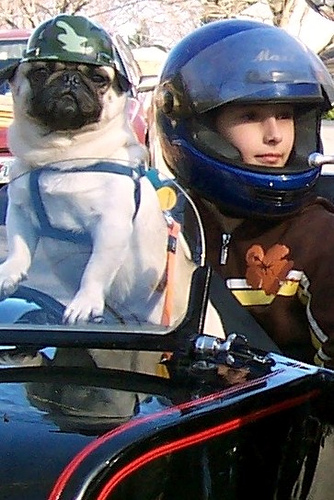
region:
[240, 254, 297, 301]
flower is on shirt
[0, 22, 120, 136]
helmet is on dog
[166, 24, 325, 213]
helmet is on person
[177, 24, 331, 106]
visor is on helmet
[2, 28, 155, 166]
the car is red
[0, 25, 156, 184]
the car behind dog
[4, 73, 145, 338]
dog behind steering wheel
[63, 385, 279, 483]
the stripe is red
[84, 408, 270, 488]
stripe is on vehicle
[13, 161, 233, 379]
windshield on the vehicle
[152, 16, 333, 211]
A woman with a blue helmet.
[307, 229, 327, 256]
Part of the jacket.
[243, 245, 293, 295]
A flower on the jacket.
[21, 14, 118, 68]
A green helmet.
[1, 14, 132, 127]
A dog wearing a helmet.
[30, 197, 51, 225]
Part of the dog harness.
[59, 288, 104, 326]
The dog's white paw.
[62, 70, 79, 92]
The dog's black nose.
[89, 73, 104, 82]
The eye of the dog.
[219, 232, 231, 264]
A silver zipper.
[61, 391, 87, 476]
This vehicle has a bright, black color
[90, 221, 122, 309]
This dog has a light grey coat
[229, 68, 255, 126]
This person is wearing a blue helmet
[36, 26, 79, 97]
This dog has a helmet on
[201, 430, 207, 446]
There is a red stripe that is on the car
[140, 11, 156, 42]
There are some bright trees in the background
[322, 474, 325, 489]
There is some concrete visible here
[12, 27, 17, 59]
There is a red car that is visible here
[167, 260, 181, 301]
There is an orange leash here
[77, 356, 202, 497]
Jackson Mingus took this photo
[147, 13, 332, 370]
young girl wearing a blue helmet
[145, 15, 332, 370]
young girl wearing a brown jacket with white and yellow stripe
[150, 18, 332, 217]
young girls blue helmet with face shield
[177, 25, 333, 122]
clear face shield on the blue helmet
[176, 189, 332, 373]
Brown jacket with yellow and white stripe the girl is wearing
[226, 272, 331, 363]
white stripe on the childs brown jacket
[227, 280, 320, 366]
yellow stripe on the childs brown jacket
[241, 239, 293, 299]
light brown orangish colored flower on childs jacket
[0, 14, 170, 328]
small white dog wearing a camo style hat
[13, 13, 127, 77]
hat that the dog is wearing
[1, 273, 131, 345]
paws on the wheel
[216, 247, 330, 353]
stripes on the sweater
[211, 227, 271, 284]
zipper on the sweater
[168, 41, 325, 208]
the helmet is blue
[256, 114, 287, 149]
nose on the face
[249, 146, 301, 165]
mouth on the face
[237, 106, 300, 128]
eyes on the face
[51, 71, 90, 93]
black nose on dog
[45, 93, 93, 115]
the mouth is droopy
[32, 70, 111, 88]
dog eyes are black